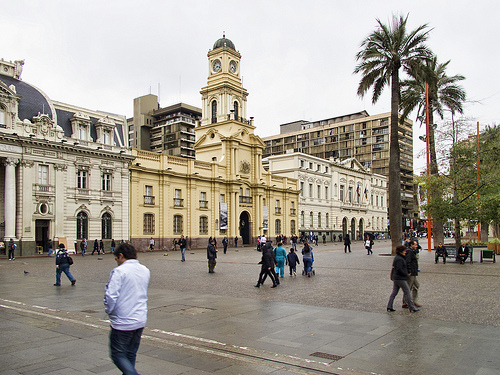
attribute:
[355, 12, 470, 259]
trees — large, tall, green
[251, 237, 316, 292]
people — walking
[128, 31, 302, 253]
building — yellow, residential, odd, old, beige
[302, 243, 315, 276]
woman — walking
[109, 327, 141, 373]
jeans — blue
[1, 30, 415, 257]
buildings — stone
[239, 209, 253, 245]
doorways — arched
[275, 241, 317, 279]
family — walking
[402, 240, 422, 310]
man — walking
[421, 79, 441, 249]
pole — attached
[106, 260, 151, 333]
shirt — white